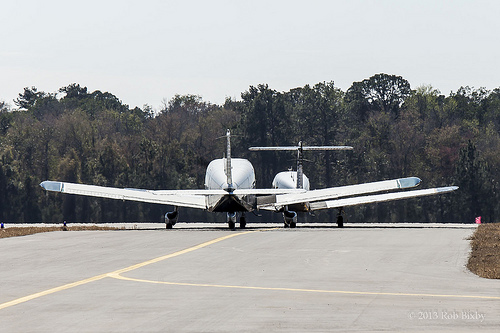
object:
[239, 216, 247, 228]
landing gear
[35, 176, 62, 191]
tip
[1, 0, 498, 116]
blue sky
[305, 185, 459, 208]
wing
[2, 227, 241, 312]
line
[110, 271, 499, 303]
line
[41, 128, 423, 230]
airplanes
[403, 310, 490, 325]
lettering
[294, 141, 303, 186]
tail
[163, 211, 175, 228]
landing gear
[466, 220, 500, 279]
grass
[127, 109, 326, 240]
white plane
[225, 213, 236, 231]
gear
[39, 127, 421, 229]
plane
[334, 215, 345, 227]
landing gear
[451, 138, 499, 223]
trees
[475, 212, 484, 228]
red object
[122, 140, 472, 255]
plane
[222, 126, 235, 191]
tail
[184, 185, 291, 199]
wing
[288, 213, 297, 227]
gear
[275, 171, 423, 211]
wing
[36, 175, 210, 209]
wing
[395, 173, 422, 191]
tip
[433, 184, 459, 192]
tip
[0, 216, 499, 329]
ground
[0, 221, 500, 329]
pavement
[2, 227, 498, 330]
runway